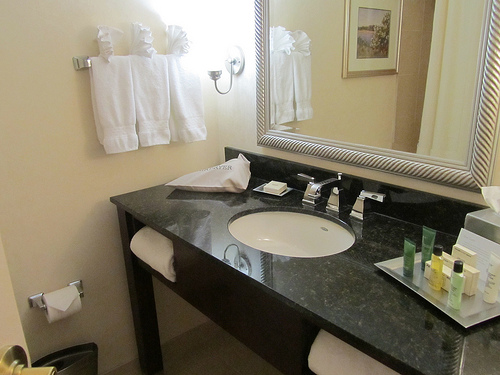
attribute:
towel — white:
[165, 52, 212, 145]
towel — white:
[126, 52, 176, 150]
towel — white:
[87, 53, 144, 156]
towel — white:
[162, 23, 194, 61]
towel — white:
[128, 18, 157, 61]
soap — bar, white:
[263, 177, 290, 196]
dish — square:
[252, 179, 295, 199]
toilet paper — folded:
[40, 283, 84, 325]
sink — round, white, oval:
[222, 203, 359, 260]